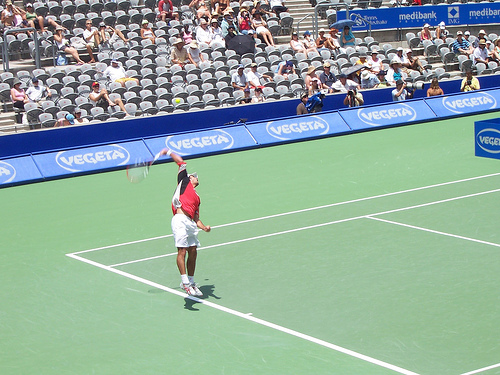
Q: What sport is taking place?
A: Tennis.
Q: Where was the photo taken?
A: Tennis match.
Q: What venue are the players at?
A: Tennis court.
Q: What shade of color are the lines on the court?
A: White.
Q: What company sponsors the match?
A: Vegeta.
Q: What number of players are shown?
A: 1.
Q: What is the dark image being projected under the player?
A: Shadow.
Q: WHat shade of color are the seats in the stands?
A: Grey.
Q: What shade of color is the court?
A: Green.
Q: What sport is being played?
A: Tennis.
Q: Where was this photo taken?
A: On a tennis court.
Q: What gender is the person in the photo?
A: Male.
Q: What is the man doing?
A: Jumping in air.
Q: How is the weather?
A: Sunny.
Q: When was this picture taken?
A: During the day.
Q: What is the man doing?
A: Playing tennis.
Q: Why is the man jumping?
A: To hit a tennis ball.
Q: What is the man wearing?
A: A t-shirt and shorts.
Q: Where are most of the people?
A: In bleachers around the field.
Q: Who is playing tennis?
A: The man on the field.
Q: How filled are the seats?
A: Sparsely filled.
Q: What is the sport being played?
A: Tennis.